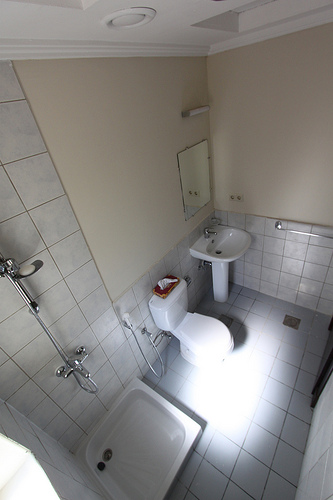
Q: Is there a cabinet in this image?
A: No, there are no cabinets.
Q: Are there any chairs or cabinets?
A: No, there are no cabinets or chairs.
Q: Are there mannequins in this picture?
A: No, there are no mannequins.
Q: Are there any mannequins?
A: No, there are no mannequins.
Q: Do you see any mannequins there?
A: No, there are no mannequins.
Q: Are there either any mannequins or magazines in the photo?
A: No, there are no mannequins or magazines.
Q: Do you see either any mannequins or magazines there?
A: No, there are no mannequins or magazines.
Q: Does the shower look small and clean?
A: Yes, the shower is small and clean.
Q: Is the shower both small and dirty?
A: No, the shower is small but clean.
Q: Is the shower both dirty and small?
A: No, the shower is small but clean.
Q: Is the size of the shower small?
A: Yes, the shower is small.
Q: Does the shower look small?
A: Yes, the shower is small.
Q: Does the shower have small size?
A: Yes, the shower is small.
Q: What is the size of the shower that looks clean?
A: The shower is small.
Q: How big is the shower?
A: The shower is small.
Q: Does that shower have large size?
A: No, the shower is small.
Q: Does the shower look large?
A: No, the shower is small.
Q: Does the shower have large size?
A: No, the shower is small.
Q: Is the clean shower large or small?
A: The shower is small.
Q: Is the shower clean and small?
A: Yes, the shower is clean and small.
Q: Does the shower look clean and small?
A: Yes, the shower is clean and small.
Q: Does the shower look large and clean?
A: No, the shower is clean but small.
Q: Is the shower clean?
A: Yes, the shower is clean.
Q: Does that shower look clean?
A: Yes, the shower is clean.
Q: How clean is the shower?
A: The shower is clean.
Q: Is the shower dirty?
A: No, the shower is clean.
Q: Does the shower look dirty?
A: No, the shower is clean.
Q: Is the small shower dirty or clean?
A: The shower is clean.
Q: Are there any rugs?
A: No, there are no rugs.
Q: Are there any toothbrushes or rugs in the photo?
A: No, there are no rugs or toothbrushes.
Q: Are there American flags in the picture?
A: No, there are no American flags.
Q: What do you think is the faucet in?
A: The faucet is in the shower.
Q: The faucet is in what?
A: The faucet is in the shower.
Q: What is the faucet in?
A: The faucet is in the shower.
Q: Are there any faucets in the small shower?
A: Yes, there is a faucet in the shower.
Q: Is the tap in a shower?
A: Yes, the tap is in a shower.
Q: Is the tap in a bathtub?
A: No, the tap is in a shower.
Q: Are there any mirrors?
A: Yes, there is a mirror.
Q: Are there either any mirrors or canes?
A: Yes, there is a mirror.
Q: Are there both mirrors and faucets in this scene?
A: Yes, there are both a mirror and a faucet.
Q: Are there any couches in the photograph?
A: No, there are no couches.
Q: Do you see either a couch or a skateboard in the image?
A: No, there are no couches or skateboards.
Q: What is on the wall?
A: The mirror is on the wall.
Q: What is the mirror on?
A: The mirror is on the wall.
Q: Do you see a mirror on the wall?
A: Yes, there is a mirror on the wall.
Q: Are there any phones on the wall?
A: No, there is a mirror on the wall.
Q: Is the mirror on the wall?
A: Yes, the mirror is on the wall.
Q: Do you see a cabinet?
A: No, there are no cabinets.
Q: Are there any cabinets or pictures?
A: No, there are no cabinets or pictures.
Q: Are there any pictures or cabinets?
A: No, there are no cabinets or pictures.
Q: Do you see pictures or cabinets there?
A: No, there are no cabinets or pictures.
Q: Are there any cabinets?
A: No, there are no cabinets.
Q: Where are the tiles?
A: The tiles are on the floor.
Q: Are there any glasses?
A: No, there are no glasses.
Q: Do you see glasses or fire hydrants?
A: No, there are no glasses or fire hydrants.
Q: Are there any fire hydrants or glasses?
A: No, there are no glasses or fire hydrants.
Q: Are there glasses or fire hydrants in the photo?
A: No, there are no glasses or fire hydrants.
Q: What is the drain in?
A: The drain is in the shower.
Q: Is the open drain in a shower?
A: Yes, the drain is in a shower.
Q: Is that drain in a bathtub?
A: No, the drain is in a shower.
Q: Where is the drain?
A: The drain is on the floor.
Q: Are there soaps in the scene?
A: Yes, there is a soap.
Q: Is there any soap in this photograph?
A: Yes, there is a soap.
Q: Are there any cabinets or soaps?
A: Yes, there is a soap.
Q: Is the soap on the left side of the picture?
A: Yes, the soap is on the left of the image.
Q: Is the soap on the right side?
A: No, the soap is on the left of the image.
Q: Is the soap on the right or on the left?
A: The soap is on the left of the image.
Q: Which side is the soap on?
A: The soap is on the left of the image.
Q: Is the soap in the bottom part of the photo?
A: Yes, the soap is in the bottom of the image.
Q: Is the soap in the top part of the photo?
A: No, the soap is in the bottom of the image.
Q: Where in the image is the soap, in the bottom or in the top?
A: The soap is in the bottom of the image.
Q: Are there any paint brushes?
A: No, there are no paint brushes.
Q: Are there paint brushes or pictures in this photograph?
A: No, there are no paint brushes or pictures.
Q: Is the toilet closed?
A: Yes, the toilet is closed.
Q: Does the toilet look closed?
A: Yes, the toilet is closed.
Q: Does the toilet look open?
A: No, the toilet is closed.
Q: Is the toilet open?
A: No, the toilet is closed.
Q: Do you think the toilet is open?
A: No, the toilet is closed.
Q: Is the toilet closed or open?
A: The toilet is closed.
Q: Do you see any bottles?
A: No, there are no bottles.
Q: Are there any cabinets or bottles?
A: No, there are no bottles or cabinets.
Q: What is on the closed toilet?
A: The tissue box is on the toilet.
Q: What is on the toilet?
A: The tissue box is on the toilet.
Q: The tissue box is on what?
A: The tissue box is on the toilet.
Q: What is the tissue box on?
A: The tissue box is on the toilet.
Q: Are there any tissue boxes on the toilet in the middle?
A: Yes, there is a tissue box on the toilet.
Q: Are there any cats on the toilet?
A: No, there is a tissue box on the toilet.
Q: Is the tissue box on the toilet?
A: Yes, the tissue box is on the toilet.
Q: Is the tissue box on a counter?
A: No, the tissue box is on the toilet.